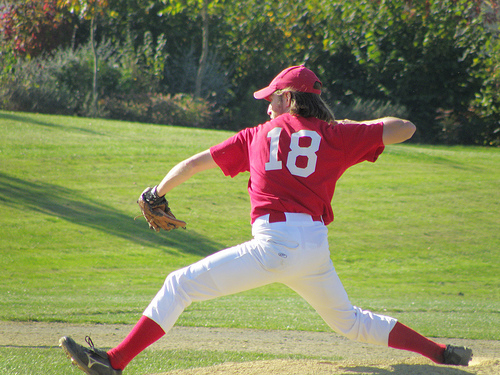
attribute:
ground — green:
[2, 110, 497, 372]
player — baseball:
[121, 36, 494, 372]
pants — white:
[138, 211, 398, 349]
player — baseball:
[59, 72, 499, 371]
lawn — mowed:
[3, 107, 498, 342]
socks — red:
[389, 320, 456, 360]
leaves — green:
[211, 0, 396, 56]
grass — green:
[6, 106, 498, 356]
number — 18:
[266, 127, 326, 180]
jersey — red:
[210, 118, 383, 223]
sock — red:
[107, 311, 165, 371]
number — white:
[258, 120, 324, 177]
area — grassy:
[41, 93, 470, 322]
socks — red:
[97, 311, 448, 370]